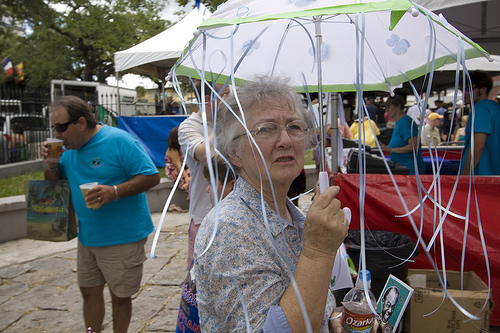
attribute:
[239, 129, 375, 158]
glasses — clear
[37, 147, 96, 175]
beer — brown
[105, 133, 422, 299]
woman — standing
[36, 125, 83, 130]
glasses — black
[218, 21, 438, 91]
umbrella — white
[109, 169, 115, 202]
bracelet — white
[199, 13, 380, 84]
umbrella — white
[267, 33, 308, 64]
umbrella — white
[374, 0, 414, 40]
ribbon — green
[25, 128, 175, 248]
beers — held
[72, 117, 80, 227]
beers — brown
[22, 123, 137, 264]
beers — brown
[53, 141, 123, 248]
beers — brown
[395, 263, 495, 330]
box — cardboard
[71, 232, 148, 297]
shorts — khaki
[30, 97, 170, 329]
man — blue-wearing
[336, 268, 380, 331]
water bottle — Ozarks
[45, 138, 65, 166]
beer cup — clear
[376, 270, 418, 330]
sign — blue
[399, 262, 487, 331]
cardboard box — brown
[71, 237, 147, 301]
shorts — khaki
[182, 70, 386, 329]
woman — old, standing, older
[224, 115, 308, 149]
eyeglasses — clear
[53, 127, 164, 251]
shirt — blue, short-sleeved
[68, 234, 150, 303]
shorts — light brown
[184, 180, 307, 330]
shirt — blue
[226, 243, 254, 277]
flowers — small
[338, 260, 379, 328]
water bottle — clear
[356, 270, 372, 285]
cap — blue, plastic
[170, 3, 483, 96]
umbrella — white, open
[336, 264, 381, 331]
bottle — clear, plastic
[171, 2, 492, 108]
umbrella — green, white, blue, pictured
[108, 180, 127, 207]
bracelet — silver 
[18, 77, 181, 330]
wrist — man's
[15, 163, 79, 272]
paper bag — brown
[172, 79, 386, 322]
female — older white adult 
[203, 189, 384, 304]
shirt — adult female flowered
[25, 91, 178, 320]
beverage — adult male drinking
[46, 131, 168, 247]
shirt — blue tee, man 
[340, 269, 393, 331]
bottle — plastic water , blue 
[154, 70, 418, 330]
woman — silver framed glasses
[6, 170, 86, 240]
bag — shopping ,  man's arm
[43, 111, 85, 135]
sunglasses — black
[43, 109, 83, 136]
glasses — black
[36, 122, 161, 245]
shirt — blue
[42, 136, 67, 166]
cup — of beer, being sipped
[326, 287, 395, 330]
hands — womans